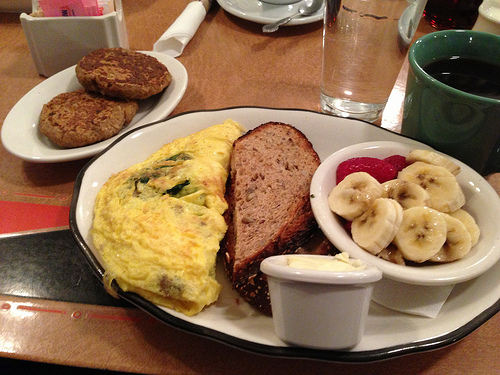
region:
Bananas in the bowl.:
[327, 145, 485, 268]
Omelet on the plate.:
[90, 116, 241, 311]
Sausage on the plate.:
[25, 40, 166, 146]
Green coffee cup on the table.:
[400, 27, 495, 174]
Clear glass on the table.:
[315, 0, 425, 125]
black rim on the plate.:
[65, 100, 495, 370]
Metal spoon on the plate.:
[260, 0, 324, 34]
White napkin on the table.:
[151, 3, 220, 59]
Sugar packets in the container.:
[22, 0, 130, 81]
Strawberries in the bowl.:
[309, 139, 497, 287]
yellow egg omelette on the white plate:
[91, 120, 243, 314]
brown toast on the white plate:
[225, 120, 332, 311]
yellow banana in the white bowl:
[326, 147, 482, 263]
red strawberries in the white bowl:
[334, 154, 413, 186]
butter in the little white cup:
[278, 250, 365, 273]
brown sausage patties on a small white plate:
[37, 49, 173, 148]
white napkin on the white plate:
[368, 275, 458, 317]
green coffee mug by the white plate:
[398, 25, 498, 178]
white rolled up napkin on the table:
[149, 0, 207, 57]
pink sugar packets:
[36, 0, 102, 23]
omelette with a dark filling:
[89, 117, 229, 346]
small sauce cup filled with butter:
[257, 250, 382, 355]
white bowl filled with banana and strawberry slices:
[310, 136, 499, 284]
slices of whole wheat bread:
[231, 118, 322, 317]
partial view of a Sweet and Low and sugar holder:
[22, 0, 124, 79]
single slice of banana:
[395, 205, 447, 260]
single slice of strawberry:
[333, 156, 397, 183]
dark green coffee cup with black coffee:
[396, 26, 498, 179]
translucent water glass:
[316, 1, 426, 134]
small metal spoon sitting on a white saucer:
[260, 1, 326, 36]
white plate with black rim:
[66, 103, 498, 366]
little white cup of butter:
[259, 249, 383, 346]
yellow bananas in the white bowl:
[326, 148, 481, 260]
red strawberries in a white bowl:
[333, 153, 408, 185]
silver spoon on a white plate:
[260, 0, 323, 35]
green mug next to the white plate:
[399, 27, 499, 177]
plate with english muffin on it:
[0, 29, 200, 170]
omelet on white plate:
[89, 108, 251, 317]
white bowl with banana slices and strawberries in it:
[300, 130, 495, 292]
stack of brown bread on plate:
[217, 98, 332, 320]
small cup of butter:
[245, 230, 396, 357]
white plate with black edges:
[65, 95, 499, 362]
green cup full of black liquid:
[398, 13, 499, 176]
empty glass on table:
[304, 0, 433, 125]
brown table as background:
[2, 0, 483, 372]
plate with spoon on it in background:
[213, 0, 340, 39]